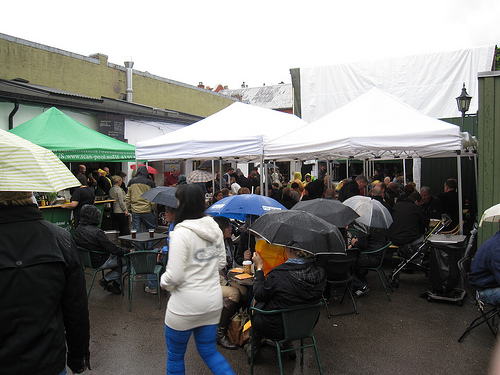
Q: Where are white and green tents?
A: Over the people.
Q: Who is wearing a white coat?
A: Woman walking.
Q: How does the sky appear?
A: Overcast.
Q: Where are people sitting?
A: On chairs.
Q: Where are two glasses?
A: On a table.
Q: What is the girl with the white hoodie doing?
A: Walking.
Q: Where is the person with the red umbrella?
A: Next to the white canopy.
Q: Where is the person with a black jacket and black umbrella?
A: Next to the woman walking.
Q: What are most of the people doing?
A: Sitting down.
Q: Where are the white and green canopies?
A: Between buildings.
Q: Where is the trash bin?
A: Next to the green wall.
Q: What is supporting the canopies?
A: Metal frames.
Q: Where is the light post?
A: Next to the white canopy.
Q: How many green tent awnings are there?
A: One.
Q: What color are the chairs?
A: Black.